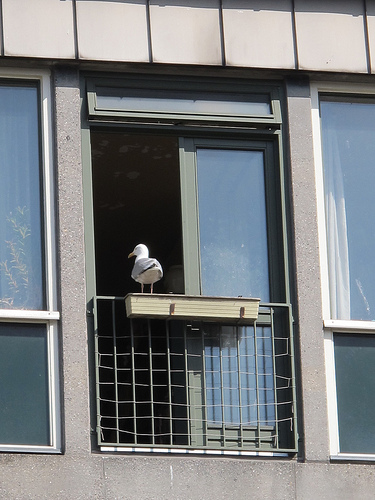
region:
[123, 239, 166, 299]
a sea bird on a window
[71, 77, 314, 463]
a window of a building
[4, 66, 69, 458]
a window with white frame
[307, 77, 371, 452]
a curtain behind a window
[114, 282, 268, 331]
a pot on a window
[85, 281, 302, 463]
a rail in front a window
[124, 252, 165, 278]
wings of seabird is gray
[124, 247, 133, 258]
a yellow beak of bird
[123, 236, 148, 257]
head of bird is white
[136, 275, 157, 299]
two legs of bird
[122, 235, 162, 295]
A pigeon stands on a windowsill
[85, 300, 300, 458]
grates cover the outside of the window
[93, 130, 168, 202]
The ceiling has peeling paint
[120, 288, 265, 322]
A wooden block is in the window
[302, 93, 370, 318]
A side window has a white curtain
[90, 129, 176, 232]
The interior is dark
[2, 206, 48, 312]
There is a plant inside the left window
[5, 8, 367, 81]
There is a tile pattern above the windows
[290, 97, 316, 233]
The building is grey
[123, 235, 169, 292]
The bird faces the interior of the building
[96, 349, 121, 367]
Hole in the fence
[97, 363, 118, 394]
Hole in the fence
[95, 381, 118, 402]
Hole in the fence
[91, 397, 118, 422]
Hole in the fence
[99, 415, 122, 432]
Hole in the fence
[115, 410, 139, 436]
Hole in the fence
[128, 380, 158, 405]
Hole in the fence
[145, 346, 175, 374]
Hole in the fence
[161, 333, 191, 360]
Hole in the fence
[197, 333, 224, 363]
Hole in the fence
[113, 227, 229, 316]
Bird on the ledge.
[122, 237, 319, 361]
Bird on the flower box.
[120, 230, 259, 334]
White bird on the flower box.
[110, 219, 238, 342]
Seagull on the flower box.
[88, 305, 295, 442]
Wire on the window.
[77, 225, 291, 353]
White seagull on the flower box.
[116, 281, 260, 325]
Flower box on the window.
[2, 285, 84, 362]
Frame of the window.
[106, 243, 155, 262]
Beak on the bird.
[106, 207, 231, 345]
Bird.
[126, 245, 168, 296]
seagull sitting on flower box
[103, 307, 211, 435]
gray grill covering window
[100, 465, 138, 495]
building is gray and rough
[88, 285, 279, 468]
open window of building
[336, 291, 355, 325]
white curtain at window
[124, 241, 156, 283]
seagull is white and black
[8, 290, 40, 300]
brown plant behind window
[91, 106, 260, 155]
small window at top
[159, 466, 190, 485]
white mark on building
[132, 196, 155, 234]
dark interior of apartment